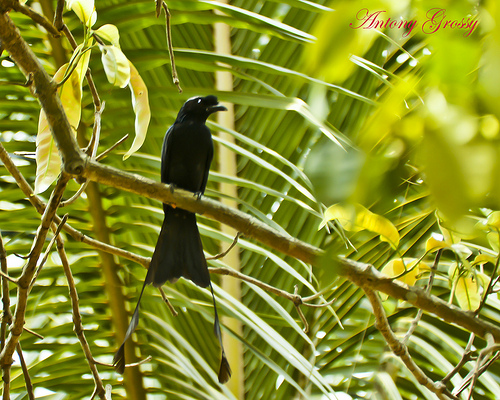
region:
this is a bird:
[159, 83, 235, 178]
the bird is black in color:
[158, 86, 230, 183]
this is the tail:
[149, 222, 199, 284]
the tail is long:
[150, 216, 202, 286]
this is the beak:
[208, 102, 236, 114]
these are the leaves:
[249, 32, 349, 192]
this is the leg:
[164, 184, 206, 201]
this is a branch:
[49, 97, 77, 165]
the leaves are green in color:
[249, 14, 322, 171]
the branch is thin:
[54, 127, 87, 184]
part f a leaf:
[215, 317, 231, 348]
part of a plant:
[317, 249, 361, 361]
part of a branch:
[221, 205, 248, 230]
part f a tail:
[174, 245, 203, 291]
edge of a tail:
[170, 235, 190, 257]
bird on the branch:
[112, 40, 236, 312]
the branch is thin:
[260, 234, 395, 298]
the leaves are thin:
[27, 253, 129, 387]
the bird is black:
[157, 126, 195, 184]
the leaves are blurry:
[373, 68, 495, 198]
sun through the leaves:
[233, 212, 330, 385]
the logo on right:
[318, 0, 483, 45]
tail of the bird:
[126, 248, 198, 286]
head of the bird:
[130, 85, 247, 126]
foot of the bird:
[167, 181, 182, 196]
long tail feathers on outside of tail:
[112, 281, 230, 386]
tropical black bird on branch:
[115, 92, 232, 382]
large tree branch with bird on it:
[0, 0, 499, 399]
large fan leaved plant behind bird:
[0, 0, 437, 397]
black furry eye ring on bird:
[204, 94, 218, 106]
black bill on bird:
[206, 102, 228, 112]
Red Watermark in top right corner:
[347, 7, 480, 39]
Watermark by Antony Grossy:
[347, 9, 482, 41]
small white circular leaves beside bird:
[56, 0, 130, 93]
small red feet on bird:
[166, 182, 205, 211]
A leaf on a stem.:
[113, 199, 350, 327]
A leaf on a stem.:
[126, 299, 234, 387]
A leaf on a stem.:
[124, 326, 214, 392]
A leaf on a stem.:
[130, 338, 192, 380]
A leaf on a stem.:
[129, 347, 203, 382]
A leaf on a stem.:
[138, 366, 220, 392]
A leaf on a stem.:
[143, 382, 190, 399]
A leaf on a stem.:
[91, 140, 366, 240]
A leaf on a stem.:
[103, 115, 353, 255]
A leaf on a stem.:
[78, 83, 368, 163]